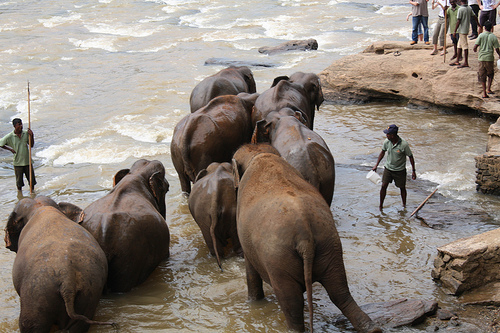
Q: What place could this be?
A: It is a lake.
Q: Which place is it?
A: It is a lake.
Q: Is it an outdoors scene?
A: Yes, it is outdoors.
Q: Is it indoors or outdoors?
A: It is outdoors.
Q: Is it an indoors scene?
A: No, it is outdoors.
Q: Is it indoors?
A: No, it is outdoors.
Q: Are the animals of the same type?
A: Yes, all the animals are elephants.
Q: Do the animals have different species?
A: No, all the animals are elephants.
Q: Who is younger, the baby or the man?
A: The baby is younger than the man.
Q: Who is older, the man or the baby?
A: The man is older than the baby.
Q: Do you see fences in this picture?
A: No, there are no fences.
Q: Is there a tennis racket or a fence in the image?
A: No, there are no fences or rackets.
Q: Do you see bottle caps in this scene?
A: No, there are no bottle caps.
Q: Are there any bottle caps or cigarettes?
A: No, there are no bottle caps or cigarettes.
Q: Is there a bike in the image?
A: No, there are no bikes.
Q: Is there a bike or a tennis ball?
A: No, there are no bikes or tennis balls.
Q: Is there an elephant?
A: Yes, there are elephants.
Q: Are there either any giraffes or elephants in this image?
A: Yes, there are elephants.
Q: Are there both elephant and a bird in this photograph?
A: No, there are elephants but no birds.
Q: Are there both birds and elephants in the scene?
A: No, there are elephants but no birds.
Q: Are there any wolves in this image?
A: No, there are no wolves.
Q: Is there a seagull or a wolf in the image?
A: No, there are no wolves or seagulls.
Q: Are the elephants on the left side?
A: Yes, the elephants are on the left of the image.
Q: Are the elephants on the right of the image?
A: No, the elephants are on the left of the image.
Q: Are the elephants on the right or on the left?
A: The elephants are on the left of the image.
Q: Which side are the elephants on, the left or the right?
A: The elephants are on the left of the image.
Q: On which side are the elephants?
A: The elephants are on the left of the image.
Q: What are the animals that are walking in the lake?
A: The animals are elephants.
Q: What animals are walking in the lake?
A: The animals are elephants.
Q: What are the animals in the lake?
A: The animals are elephants.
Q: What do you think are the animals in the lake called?
A: The animals are elephants.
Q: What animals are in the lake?
A: The animals are elephants.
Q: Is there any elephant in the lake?
A: Yes, there are elephants in the lake.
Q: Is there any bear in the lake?
A: No, there are elephants in the lake.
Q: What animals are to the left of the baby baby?
A: The animals are elephants.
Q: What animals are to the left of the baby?
A: The animals are elephants.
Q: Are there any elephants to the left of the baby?
A: Yes, there are elephants to the left of the baby.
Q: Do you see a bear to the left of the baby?
A: No, there are elephants to the left of the baby.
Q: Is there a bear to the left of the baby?
A: No, there are elephants to the left of the baby.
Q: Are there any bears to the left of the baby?
A: No, there are elephants to the left of the baby.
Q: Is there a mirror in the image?
A: No, there are no mirrors.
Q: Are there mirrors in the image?
A: No, there are no mirrors.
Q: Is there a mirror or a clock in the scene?
A: No, there are no mirrors or clocks.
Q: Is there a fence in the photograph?
A: No, there are no fences.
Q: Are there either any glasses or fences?
A: No, there are no fences or glasses.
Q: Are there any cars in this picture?
A: No, there are no cars.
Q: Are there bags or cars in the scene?
A: No, there are no cars or bags.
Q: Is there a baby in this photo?
A: Yes, there is a baby.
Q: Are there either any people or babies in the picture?
A: Yes, there is a baby.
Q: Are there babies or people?
A: Yes, there is a baby.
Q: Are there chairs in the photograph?
A: No, there are no chairs.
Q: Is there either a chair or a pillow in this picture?
A: No, there are no chairs or pillows.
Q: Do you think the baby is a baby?
A: Yes, the baby is a baby.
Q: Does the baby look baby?
A: Yes, the baby is a baby.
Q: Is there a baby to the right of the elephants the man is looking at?
A: Yes, there is a baby to the right of the elephants.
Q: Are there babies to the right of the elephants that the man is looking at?
A: Yes, there is a baby to the right of the elephants.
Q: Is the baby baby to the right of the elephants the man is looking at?
A: Yes, the baby is to the right of the elephants.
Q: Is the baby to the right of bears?
A: No, the baby is to the right of the elephants.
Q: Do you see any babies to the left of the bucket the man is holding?
A: Yes, there is a baby to the left of the bucket.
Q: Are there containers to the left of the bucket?
A: No, there is a baby to the left of the bucket.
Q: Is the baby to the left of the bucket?
A: Yes, the baby is to the left of the bucket.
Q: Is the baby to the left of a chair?
A: No, the baby is to the left of the bucket.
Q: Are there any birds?
A: No, there are no birds.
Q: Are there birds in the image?
A: No, there are no birds.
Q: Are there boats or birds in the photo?
A: No, there are no birds or boats.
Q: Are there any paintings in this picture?
A: No, there are no paintings.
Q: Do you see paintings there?
A: No, there are no paintings.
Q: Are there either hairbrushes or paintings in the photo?
A: No, there are no paintings or hairbrushes.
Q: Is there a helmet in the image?
A: No, there are no helmets.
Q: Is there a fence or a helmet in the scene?
A: No, there are no helmets or fences.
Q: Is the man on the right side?
A: Yes, the man is on the right of the image.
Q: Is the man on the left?
A: No, the man is on the right of the image.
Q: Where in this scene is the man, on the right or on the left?
A: The man is on the right of the image.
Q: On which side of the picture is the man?
A: The man is on the right of the image.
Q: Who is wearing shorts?
A: The man is wearing shorts.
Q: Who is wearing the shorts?
A: The man is wearing shorts.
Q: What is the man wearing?
A: The man is wearing shorts.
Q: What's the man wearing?
A: The man is wearing shorts.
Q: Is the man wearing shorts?
A: Yes, the man is wearing shorts.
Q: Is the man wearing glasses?
A: No, the man is wearing shorts.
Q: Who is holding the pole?
A: The man is holding the pole.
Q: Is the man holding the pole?
A: Yes, the man is holding the pole.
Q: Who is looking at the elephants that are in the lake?
A: The man is looking at the elephants.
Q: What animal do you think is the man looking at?
A: The man is looking at the elephants.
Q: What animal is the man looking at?
A: The man is looking at the elephants.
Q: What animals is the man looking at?
A: The man is looking at the elephants.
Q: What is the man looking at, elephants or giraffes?
A: The man is looking at elephants.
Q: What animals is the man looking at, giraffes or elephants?
A: The man is looking at elephants.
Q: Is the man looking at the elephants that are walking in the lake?
A: Yes, the man is looking at the elephants.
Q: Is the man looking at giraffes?
A: No, the man is looking at the elephants.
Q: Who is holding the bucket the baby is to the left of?
A: The man is holding the bucket.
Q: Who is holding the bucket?
A: The man is holding the bucket.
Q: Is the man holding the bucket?
A: Yes, the man is holding the bucket.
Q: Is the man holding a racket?
A: No, the man is holding the bucket.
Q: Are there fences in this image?
A: No, there are no fences.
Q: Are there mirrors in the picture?
A: No, there are no mirrors.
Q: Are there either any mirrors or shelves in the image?
A: No, there are no mirrors or shelves.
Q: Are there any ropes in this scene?
A: No, there are no ropes.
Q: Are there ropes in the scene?
A: No, there are no ropes.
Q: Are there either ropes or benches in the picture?
A: No, there are no ropes or benches.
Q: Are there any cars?
A: No, there are no cars.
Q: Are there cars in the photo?
A: No, there are no cars.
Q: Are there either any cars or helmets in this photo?
A: No, there are no cars or helmets.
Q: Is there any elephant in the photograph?
A: Yes, there is an elephant.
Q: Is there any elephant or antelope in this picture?
A: Yes, there is an elephant.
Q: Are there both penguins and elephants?
A: No, there is an elephant but no penguins.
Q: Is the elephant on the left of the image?
A: Yes, the elephant is on the left of the image.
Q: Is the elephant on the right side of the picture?
A: No, the elephant is on the left of the image.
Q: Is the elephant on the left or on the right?
A: The elephant is on the left of the image.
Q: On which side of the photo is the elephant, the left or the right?
A: The elephant is on the left of the image.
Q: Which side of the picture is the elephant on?
A: The elephant is on the left of the image.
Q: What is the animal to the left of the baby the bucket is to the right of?
A: The animal is an elephant.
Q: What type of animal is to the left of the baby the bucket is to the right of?
A: The animal is an elephant.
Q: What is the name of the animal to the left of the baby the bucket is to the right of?
A: The animal is an elephant.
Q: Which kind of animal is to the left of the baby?
A: The animal is an elephant.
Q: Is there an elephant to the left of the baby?
A: Yes, there is an elephant to the left of the baby.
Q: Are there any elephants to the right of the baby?
A: No, the elephant is to the left of the baby.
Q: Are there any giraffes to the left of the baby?
A: No, there is an elephant to the left of the baby.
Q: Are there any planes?
A: No, there are no planes.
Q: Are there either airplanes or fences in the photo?
A: No, there are no airplanes or fences.